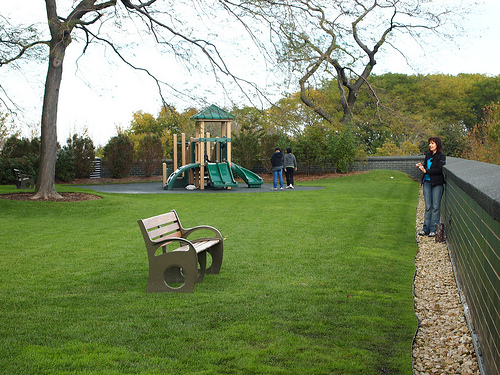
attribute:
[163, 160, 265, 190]
slides — green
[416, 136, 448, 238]
woman — smiling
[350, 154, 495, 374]
wall — black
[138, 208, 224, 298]
bench — empty, brown, grey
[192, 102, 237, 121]
playground — green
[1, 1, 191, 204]
tree — tall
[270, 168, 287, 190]
jeans — green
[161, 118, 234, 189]
gilded — brown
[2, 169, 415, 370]
grass — green, trimmed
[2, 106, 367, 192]
trees — green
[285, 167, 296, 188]
pants — black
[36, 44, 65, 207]
trunk — grey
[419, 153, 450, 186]
jacket — black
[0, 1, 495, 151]
sky — cloudy